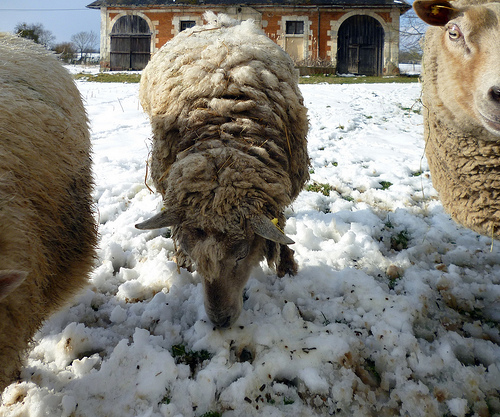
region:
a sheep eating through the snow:
[129, 14, 308, 331]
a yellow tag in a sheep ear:
[268, 207, 288, 233]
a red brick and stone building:
[83, 2, 421, 86]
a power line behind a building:
[0, 3, 88, 16]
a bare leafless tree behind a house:
[73, 26, 92, 61]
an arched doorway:
[329, 6, 467, 83]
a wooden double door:
[106, 16, 152, 71]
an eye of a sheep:
[438, 22, 461, 44]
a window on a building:
[278, 13, 313, 35]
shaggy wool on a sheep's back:
[177, 4, 322, 121]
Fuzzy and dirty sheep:
[122, 21, 332, 317]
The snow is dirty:
[292, 247, 467, 414]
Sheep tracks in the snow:
[140, 321, 296, 392]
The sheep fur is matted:
[155, 80, 277, 259]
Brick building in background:
[92, 3, 430, 88]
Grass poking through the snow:
[314, 173, 353, 224]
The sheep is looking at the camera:
[410, 3, 499, 138]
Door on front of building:
[107, 15, 157, 81]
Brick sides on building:
[313, 16, 335, 59]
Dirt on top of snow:
[276, 327, 322, 362]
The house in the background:
[98, 7, 412, 86]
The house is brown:
[98, 7, 411, 86]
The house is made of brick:
[94, 4, 427, 63]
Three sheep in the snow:
[21, 12, 494, 408]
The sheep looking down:
[138, 187, 311, 337]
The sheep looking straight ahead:
[411, 5, 499, 142]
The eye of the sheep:
[445, 17, 467, 51]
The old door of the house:
[108, 14, 150, 75]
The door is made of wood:
[107, 14, 154, 75]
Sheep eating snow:
[133, 15, 335, 349]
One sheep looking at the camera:
[403, 1, 499, 266]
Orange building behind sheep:
[91, 0, 418, 109]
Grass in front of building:
[84, 61, 421, 110]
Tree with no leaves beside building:
[62, 24, 102, 67]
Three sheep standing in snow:
[3, 19, 497, 353]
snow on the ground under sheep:
[46, 62, 439, 396]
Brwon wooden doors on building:
[100, 9, 156, 72]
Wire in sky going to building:
[11, 1, 111, 22]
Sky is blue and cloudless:
[3, 6, 441, 56]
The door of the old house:
[333, 15, 397, 80]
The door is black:
[335, 20, 387, 78]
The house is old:
[87, 2, 418, 86]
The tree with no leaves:
[68, 27, 95, 66]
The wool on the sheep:
[163, 22, 310, 172]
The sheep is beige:
[141, 19, 337, 319]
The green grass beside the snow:
[103, 70, 140, 85]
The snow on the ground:
[327, 101, 418, 276]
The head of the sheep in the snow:
[141, 63, 310, 326]